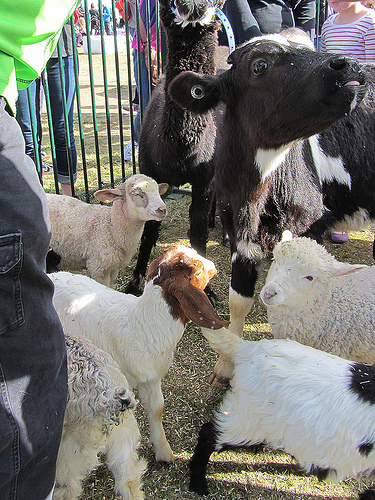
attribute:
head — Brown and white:
[144, 242, 231, 329]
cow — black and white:
[165, 31, 373, 389]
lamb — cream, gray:
[43, 175, 167, 277]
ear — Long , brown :
[168, 275, 235, 331]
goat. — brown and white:
[42, 243, 229, 446]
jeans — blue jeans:
[1, 94, 100, 497]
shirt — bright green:
[4, 2, 89, 102]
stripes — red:
[318, 18, 374, 45]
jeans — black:
[0, 97, 78, 498]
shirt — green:
[0, 1, 88, 119]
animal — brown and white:
[129, 229, 237, 345]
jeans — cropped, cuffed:
[11, 54, 84, 194]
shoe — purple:
[330, 229, 350, 242]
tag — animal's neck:
[208, 0, 256, 78]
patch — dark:
[127, 186, 148, 207]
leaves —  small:
[167, 410, 184, 430]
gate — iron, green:
[47, 23, 153, 154]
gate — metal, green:
[25, 2, 163, 207]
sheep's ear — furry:
[334, 259, 369, 281]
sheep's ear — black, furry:
[166, 66, 222, 115]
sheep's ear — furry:
[91, 184, 121, 205]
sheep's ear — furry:
[166, 276, 231, 330]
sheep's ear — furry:
[155, 178, 171, 198]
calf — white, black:
[163, 23, 372, 404]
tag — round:
[345, 113, 358, 176]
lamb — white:
[259, 226, 373, 362]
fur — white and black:
[52, 302, 188, 458]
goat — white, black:
[166, 22, 363, 337]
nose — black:
[327, 54, 363, 73]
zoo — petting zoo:
[0, 0, 373, 499]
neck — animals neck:
[161, 8, 226, 44]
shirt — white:
[318, 7, 373, 62]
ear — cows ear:
[167, 71, 231, 113]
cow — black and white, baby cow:
[169, 27, 374, 330]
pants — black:
[0, 97, 66, 499]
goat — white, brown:
[44, 242, 220, 464]